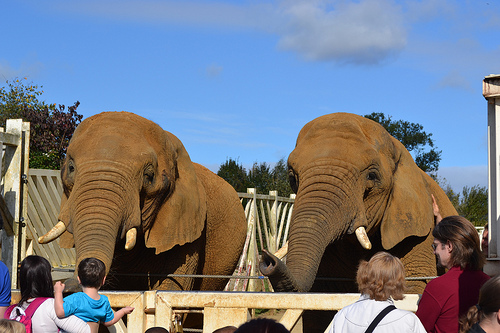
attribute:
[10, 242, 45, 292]
head — woman's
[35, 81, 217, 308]
elephant — in zoo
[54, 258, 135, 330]
boy — dark haired, young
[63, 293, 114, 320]
shirt — blue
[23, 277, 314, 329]
gate — white, metal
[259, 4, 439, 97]
cloud — white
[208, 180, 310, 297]
fence — white, metal, diagonal slats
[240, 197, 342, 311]
elephant trunk — tip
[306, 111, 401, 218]
elephant — big, gray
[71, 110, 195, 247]
elephant — big, gray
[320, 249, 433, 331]
person — shoulder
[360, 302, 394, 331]
strap — bag, black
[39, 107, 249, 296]
elephant — giant, ear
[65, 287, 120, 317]
shirt — blue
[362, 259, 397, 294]
hair — blonde